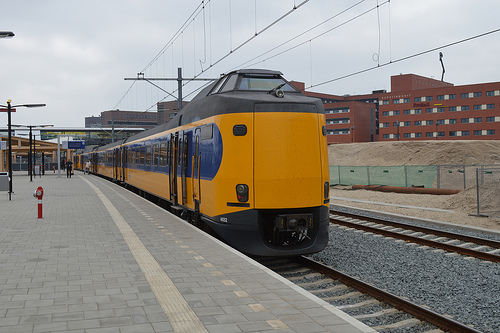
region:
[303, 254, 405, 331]
A meatlic rusty railway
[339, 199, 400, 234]
A meatlic rusty railway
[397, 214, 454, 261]
A meatlic rusty railway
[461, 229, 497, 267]
A meatlic rusty railway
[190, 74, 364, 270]
A yellow blue and grey train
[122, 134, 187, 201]
A yellow blue and grey train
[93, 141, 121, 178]
A yellow blue and grey train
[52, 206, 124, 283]
A tile cement road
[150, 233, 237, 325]
A tile cement road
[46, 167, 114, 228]
A tile cement road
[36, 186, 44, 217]
red post at train station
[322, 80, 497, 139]
brown building behind train station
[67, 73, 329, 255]
yellow and blue train at the train station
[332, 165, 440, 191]
green fence behind the train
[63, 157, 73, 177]
man in black at train station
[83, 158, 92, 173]
man in white at the train station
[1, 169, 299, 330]
grey and white brick train platform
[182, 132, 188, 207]
train has many doors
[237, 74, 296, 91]
window on front of train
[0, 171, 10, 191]
grey trash can on train platform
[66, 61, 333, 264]
a train on track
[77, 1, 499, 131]
powerlines above the train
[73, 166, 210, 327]
yellow lines on ground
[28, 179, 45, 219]
a red hydrant at station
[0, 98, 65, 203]
light poles are lined up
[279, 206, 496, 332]
two tracks at station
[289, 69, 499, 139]
a red brick building on right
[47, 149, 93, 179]
people at the station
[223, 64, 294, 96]
windshield on train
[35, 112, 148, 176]
an overpass over the train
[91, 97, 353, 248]
Train pulling into the station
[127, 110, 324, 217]
Blue and Yellow train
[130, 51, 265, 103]
Electric wires over the train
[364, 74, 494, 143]
Building behind a train station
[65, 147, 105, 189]
People waiting for a train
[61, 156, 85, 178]
Person wearing all black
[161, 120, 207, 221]
Doors on the side of a train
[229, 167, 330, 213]
headlights on a train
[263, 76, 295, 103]
windshield on a train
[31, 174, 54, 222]
Hydrant in the train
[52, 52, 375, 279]
the train was yellow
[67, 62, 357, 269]
the roof is gray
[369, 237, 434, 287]
the gravel is gray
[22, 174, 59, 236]
the hydrant is in the sidewalk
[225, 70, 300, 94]
the windshield is high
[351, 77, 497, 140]
the building is large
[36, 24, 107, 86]
the sky is gray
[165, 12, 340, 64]
the wires are black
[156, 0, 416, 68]
the wires are thick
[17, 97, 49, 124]
the light is off